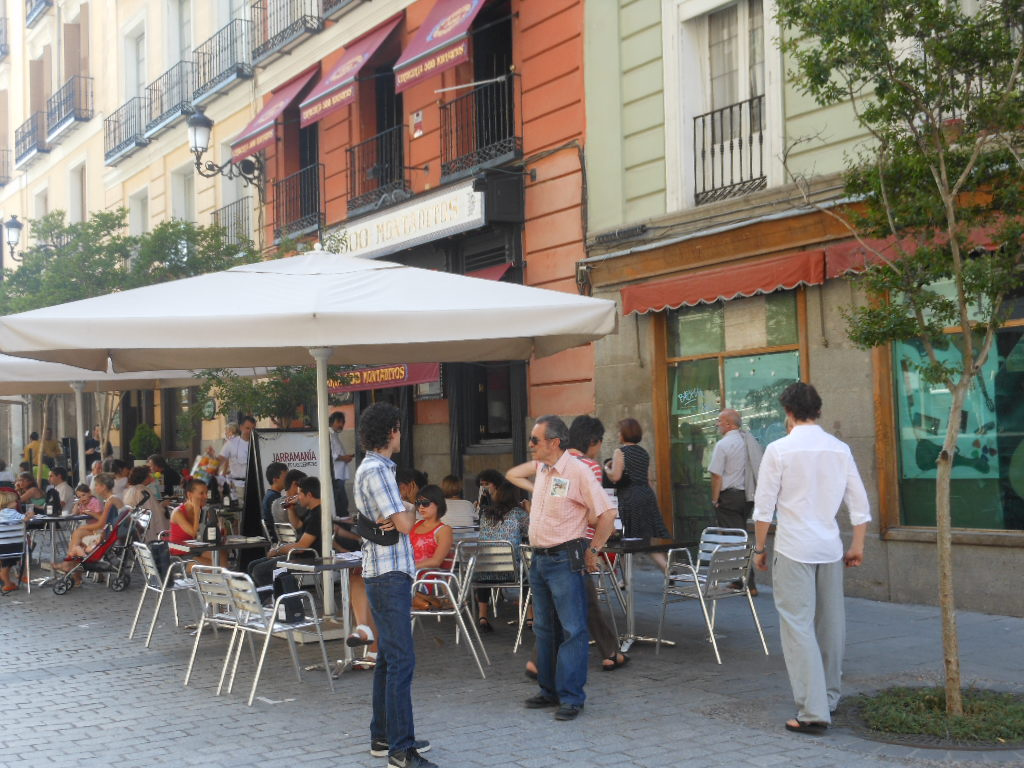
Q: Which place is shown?
A: It is a street.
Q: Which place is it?
A: It is a street.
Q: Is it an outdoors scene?
A: Yes, it is outdoors.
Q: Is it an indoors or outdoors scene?
A: It is outdoors.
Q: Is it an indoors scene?
A: No, it is outdoors.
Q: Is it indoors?
A: No, it is outdoors.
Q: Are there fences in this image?
A: No, there are no fences.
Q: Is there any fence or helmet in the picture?
A: No, there are no fences or helmets.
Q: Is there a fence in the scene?
A: No, there are no fences.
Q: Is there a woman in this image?
A: Yes, there is a woman.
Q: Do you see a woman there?
A: Yes, there is a woman.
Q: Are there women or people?
A: Yes, there is a woman.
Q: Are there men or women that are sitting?
A: Yes, the woman is sitting.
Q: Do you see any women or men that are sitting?
A: Yes, the woman is sitting.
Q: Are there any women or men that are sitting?
A: Yes, the woman is sitting.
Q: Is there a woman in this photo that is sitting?
A: Yes, there is a woman that is sitting.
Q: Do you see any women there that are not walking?
A: Yes, there is a woman that is sitting .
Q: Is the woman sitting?
A: Yes, the woman is sitting.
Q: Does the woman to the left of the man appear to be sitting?
A: Yes, the woman is sitting.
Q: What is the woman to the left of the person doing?
A: The woman is sitting.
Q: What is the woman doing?
A: The woman is sitting.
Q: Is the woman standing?
A: No, the woman is sitting.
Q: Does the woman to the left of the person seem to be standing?
A: No, the woman is sitting.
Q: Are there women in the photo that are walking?
A: No, there is a woman but she is sitting.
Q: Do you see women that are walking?
A: No, there is a woman but she is sitting.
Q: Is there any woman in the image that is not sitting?
A: No, there is a woman but she is sitting.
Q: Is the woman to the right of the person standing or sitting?
A: The woman is sitting.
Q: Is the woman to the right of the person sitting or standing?
A: The woman is sitting.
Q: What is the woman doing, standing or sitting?
A: The woman is sitting.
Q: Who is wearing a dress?
A: The woman is wearing a dress.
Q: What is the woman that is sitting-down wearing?
A: The woman is wearing a dress.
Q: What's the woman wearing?
A: The woman is wearing a dress.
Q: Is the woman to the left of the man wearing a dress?
A: Yes, the woman is wearing a dress.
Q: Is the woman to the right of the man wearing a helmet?
A: No, the woman is wearing a dress.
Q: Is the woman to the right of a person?
A: Yes, the woman is to the right of a person.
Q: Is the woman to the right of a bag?
A: No, the woman is to the right of a person.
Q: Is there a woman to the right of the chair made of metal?
A: Yes, there is a woman to the right of the chair.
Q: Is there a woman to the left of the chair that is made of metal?
A: No, the woman is to the right of the chair.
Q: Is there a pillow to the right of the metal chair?
A: No, there is a woman to the right of the chair.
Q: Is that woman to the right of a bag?
A: No, the woman is to the right of the chair.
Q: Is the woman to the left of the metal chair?
A: No, the woman is to the right of the chair.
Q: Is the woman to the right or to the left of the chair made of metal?
A: The woman is to the right of the chair.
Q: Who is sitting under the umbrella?
A: The woman is sitting under the umbrella.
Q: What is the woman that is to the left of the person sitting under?
A: The woman is sitting under the umbrella.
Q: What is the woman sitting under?
A: The woman is sitting under the umbrella.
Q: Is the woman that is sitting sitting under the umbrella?
A: Yes, the woman is sitting under the umbrella.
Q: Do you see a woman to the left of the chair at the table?
A: Yes, there is a woman to the left of the chair.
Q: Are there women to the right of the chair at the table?
A: No, the woman is to the left of the chair.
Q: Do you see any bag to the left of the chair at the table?
A: No, there is a woman to the left of the chair.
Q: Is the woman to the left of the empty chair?
A: Yes, the woman is to the left of the chair.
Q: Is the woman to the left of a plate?
A: No, the woman is to the left of the chair.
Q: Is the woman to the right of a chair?
A: No, the woman is to the left of a chair.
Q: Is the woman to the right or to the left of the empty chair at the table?
A: The woman is to the left of the chair.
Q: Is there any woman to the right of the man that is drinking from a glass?
A: Yes, there is a woman to the right of the man.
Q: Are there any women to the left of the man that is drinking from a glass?
A: No, the woman is to the right of the man.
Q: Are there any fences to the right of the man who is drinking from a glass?
A: No, there is a woman to the right of the man.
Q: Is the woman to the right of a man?
A: Yes, the woman is to the right of a man.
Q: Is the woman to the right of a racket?
A: No, the woman is to the right of a man.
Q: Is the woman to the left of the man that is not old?
A: No, the woman is to the right of the man.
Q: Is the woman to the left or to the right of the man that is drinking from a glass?
A: The woman is to the right of the man.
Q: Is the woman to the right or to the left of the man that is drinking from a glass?
A: The woman is to the right of the man.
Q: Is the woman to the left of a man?
A: Yes, the woman is to the left of a man.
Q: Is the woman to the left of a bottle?
A: No, the woman is to the left of a man.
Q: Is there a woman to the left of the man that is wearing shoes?
A: Yes, there is a woman to the left of the man.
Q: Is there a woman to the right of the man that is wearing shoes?
A: No, the woman is to the left of the man.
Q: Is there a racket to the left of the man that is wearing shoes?
A: No, there is a woman to the left of the man.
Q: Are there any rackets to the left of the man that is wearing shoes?
A: No, there is a woman to the left of the man.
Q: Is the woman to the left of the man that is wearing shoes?
A: Yes, the woman is to the left of the man.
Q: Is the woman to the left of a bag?
A: No, the woman is to the left of the man.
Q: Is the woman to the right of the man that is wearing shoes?
A: No, the woman is to the left of the man.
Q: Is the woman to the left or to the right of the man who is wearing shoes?
A: The woman is to the left of the man.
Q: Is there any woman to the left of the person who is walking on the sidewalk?
A: Yes, there is a woman to the left of the person.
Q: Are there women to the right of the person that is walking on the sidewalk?
A: No, the woman is to the left of the person.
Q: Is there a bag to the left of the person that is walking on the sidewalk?
A: No, there is a woman to the left of the person.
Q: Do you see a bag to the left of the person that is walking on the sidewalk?
A: No, there is a woman to the left of the person.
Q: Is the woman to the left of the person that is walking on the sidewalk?
A: Yes, the woman is to the left of the person.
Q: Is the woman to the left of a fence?
A: No, the woman is to the left of the person.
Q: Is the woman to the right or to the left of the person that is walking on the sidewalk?
A: The woman is to the left of the person.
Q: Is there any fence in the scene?
A: No, there are no fences.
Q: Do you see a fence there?
A: No, there are no fences.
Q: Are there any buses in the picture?
A: No, there are no buses.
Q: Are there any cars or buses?
A: No, there are no buses or cars.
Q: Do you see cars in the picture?
A: No, there are no cars.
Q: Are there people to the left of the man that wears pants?
A: Yes, there is a person to the left of the man.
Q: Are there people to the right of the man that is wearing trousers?
A: No, the person is to the left of the man.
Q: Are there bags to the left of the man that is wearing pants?
A: No, there is a person to the left of the man.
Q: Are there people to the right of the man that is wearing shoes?
A: Yes, there is a person to the right of the man.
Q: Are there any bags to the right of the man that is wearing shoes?
A: No, there is a person to the right of the man.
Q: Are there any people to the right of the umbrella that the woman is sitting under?
A: Yes, there is a person to the right of the umbrella.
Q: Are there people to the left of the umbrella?
A: No, the person is to the right of the umbrella.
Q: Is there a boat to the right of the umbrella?
A: No, there is a person to the right of the umbrella.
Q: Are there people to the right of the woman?
A: Yes, there is a person to the right of the woman.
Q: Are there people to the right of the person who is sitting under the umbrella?
A: Yes, there is a person to the right of the woman.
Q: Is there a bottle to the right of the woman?
A: No, there is a person to the right of the woman.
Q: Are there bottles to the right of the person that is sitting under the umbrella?
A: No, there is a person to the right of the woman.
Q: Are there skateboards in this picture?
A: No, there are no skateboards.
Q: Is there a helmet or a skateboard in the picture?
A: No, there are no skateboards or helmets.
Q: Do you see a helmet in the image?
A: No, there are no helmets.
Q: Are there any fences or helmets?
A: No, there are no helmets or fences.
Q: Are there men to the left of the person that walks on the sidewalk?
A: Yes, there is a man to the left of the person.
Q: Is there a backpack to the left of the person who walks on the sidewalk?
A: No, there is a man to the left of the person.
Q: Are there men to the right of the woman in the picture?
A: Yes, there is a man to the right of the woman.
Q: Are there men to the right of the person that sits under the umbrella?
A: Yes, there is a man to the right of the woman.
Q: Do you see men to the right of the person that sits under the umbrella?
A: Yes, there is a man to the right of the woman.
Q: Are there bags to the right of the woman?
A: No, there is a man to the right of the woman.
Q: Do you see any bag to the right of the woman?
A: No, there is a man to the right of the woman.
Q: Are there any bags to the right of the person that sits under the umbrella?
A: No, there is a man to the right of the woman.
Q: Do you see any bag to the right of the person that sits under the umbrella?
A: No, there is a man to the right of the woman.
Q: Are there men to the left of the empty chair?
A: Yes, there is a man to the left of the chair.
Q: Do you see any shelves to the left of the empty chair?
A: No, there is a man to the left of the chair.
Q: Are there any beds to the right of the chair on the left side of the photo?
A: No, there is a man to the right of the chair.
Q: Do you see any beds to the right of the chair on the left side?
A: No, there is a man to the right of the chair.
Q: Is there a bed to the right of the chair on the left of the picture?
A: No, there is a man to the right of the chair.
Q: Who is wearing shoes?
A: The man is wearing shoes.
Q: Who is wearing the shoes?
A: The man is wearing shoes.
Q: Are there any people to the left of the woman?
A: Yes, there is a person to the left of the woman.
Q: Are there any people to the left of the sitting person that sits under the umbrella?
A: Yes, there is a person to the left of the woman.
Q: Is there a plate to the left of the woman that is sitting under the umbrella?
A: No, there is a person to the left of the woman.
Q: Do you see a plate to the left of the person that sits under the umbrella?
A: No, there is a person to the left of the woman.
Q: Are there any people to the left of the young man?
A: Yes, there is a person to the left of the man.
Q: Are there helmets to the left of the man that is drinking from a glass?
A: No, there is a person to the left of the man.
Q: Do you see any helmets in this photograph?
A: No, there are no helmets.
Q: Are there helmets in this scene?
A: No, there are no helmets.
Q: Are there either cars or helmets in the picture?
A: No, there are no helmets or cars.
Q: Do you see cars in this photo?
A: No, there are no cars.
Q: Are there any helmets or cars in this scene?
A: No, there are no cars or helmets.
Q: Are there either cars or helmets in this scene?
A: No, there are no cars or helmets.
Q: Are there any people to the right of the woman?
A: Yes, there is a person to the right of the woman.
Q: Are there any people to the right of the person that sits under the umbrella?
A: Yes, there is a person to the right of the woman.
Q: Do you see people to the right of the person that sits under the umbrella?
A: Yes, there is a person to the right of the woman.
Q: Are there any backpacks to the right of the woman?
A: No, there is a person to the right of the woman.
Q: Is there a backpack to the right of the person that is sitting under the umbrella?
A: No, there is a person to the right of the woman.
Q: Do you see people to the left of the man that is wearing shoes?
A: Yes, there is a person to the left of the man.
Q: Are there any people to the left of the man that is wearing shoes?
A: Yes, there is a person to the left of the man.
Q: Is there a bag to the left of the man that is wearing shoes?
A: No, there is a person to the left of the man.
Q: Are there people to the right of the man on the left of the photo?
A: Yes, there is a person to the right of the man.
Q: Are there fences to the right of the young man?
A: No, there is a person to the right of the man.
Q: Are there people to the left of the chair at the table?
A: Yes, there is a person to the left of the chair.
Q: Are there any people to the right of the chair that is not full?
A: No, the person is to the left of the chair.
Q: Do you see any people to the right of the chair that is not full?
A: No, the person is to the left of the chair.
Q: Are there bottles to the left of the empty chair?
A: No, there is a person to the left of the chair.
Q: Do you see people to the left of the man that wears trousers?
A: Yes, there is a person to the left of the man.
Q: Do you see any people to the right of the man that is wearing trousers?
A: No, the person is to the left of the man.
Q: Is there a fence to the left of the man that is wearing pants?
A: No, there is a person to the left of the man.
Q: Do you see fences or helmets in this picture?
A: No, there are no fences or helmets.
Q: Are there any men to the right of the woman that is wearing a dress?
A: Yes, there is a man to the right of the woman.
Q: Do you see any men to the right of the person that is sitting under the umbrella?
A: Yes, there is a man to the right of the woman.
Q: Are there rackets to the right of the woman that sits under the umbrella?
A: No, there is a man to the right of the woman.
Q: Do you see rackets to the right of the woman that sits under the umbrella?
A: No, there is a man to the right of the woman.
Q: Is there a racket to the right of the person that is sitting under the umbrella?
A: No, there is a man to the right of the woman.